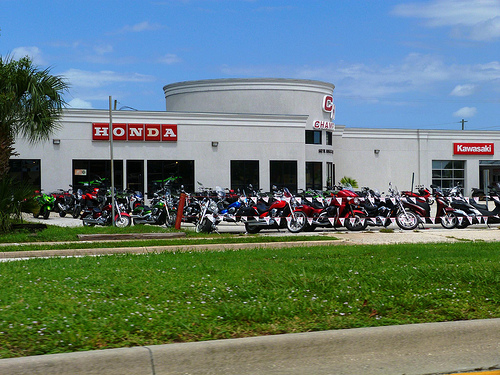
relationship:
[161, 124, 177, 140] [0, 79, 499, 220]
tile in front of building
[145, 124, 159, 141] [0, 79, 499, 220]
tile in front of building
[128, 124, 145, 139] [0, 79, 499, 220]
tile in front of building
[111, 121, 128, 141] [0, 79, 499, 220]
tile in front of building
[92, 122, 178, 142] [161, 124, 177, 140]
honda written on tile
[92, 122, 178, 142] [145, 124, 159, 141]
honda written on tile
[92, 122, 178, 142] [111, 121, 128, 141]
honda written on tile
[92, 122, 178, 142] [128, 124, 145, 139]
honda written on tile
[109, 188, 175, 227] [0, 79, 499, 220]
bike front of building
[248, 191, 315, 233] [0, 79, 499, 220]
bike front of building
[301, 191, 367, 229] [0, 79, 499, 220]
bike front of building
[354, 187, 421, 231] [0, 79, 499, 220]
bike front of building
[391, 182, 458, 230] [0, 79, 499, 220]
bike front of building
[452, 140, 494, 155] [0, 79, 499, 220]
kawasaki written on building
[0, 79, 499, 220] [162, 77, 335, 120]
building has middle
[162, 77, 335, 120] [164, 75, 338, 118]
middle has circular shape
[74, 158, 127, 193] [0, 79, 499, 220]
window in front of building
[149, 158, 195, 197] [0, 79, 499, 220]
window in front of building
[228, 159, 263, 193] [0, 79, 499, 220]
window in front of building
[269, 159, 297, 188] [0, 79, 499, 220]
window in front of building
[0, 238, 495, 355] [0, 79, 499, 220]
grass in front of building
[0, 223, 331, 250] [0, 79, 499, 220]
grass in front of building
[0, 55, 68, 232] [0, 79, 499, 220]
tree near building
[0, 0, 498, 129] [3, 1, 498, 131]
sky in background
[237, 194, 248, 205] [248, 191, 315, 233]
banner flag in front of bike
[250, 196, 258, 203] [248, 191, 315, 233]
banner flag in front of bike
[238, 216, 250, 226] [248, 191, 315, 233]
banner flag in front of bike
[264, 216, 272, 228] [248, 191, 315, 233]
banner flag in front of bike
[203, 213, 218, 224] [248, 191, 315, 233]
banner flag in front of bike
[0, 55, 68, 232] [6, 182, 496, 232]
tree ar side of lot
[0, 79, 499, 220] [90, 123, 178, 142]
building has sign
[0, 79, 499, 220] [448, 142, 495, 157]
building has sign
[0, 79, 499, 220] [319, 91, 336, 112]
building has sign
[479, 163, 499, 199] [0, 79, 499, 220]
garage in front of building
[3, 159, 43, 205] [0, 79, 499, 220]
garage in front of building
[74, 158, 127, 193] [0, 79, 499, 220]
window in building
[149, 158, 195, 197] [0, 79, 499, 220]
window in building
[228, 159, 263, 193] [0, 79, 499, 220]
window in building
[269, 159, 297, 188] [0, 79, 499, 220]
window in building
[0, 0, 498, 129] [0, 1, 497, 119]
sky has clouds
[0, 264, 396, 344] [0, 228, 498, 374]
flowers are across street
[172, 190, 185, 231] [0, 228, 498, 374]
pole marking street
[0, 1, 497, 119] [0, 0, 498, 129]
clouds are in sky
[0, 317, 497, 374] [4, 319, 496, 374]
cement on curb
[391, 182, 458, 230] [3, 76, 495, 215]
bike at dealership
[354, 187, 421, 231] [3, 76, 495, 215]
bike at dealership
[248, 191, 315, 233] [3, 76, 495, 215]
bike at dealership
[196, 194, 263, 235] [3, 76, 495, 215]
bike at dealership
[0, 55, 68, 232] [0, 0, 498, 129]
tree against sky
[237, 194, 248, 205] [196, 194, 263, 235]
banner flag in front of bike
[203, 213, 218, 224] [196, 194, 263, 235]
banner flag in front of bike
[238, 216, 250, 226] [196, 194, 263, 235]
banner flag in front of bike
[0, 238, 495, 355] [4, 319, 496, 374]
grass against curb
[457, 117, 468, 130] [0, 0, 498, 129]
pole against sky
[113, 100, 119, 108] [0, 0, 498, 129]
pole against sky